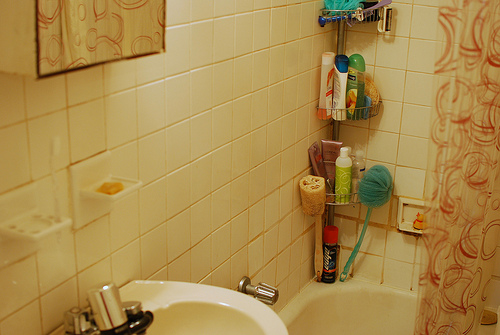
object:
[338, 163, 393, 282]
shower scrub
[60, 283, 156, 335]
faucet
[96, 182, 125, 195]
soap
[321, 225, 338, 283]
bottle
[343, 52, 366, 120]
green bottle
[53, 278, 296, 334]
sink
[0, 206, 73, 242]
toothbrush holder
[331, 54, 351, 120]
bottle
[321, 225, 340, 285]
gel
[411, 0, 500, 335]
curtain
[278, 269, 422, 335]
bath tub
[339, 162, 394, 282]
poof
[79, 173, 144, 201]
dish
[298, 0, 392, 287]
shower caddy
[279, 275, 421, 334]
white tub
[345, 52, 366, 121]
shower gel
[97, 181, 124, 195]
bar soap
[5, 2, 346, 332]
wall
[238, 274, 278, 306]
knob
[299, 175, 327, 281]
loofah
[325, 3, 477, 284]
wall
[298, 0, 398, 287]
container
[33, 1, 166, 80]
medicine cabinet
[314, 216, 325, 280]
handle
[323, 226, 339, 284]
can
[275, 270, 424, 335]
tub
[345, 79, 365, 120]
body wash